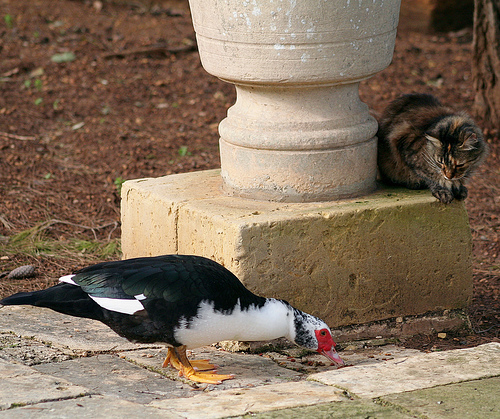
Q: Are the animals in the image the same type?
A: No, they are ducks and cats.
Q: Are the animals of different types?
A: Yes, they are ducks and cats.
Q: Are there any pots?
A: Yes, there is a pot.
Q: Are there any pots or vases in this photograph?
A: Yes, there is a pot.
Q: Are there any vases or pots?
A: Yes, there is a pot.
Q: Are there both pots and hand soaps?
A: No, there is a pot but no hand soaps.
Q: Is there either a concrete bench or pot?
A: Yes, there is a concrete pot.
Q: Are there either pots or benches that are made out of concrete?
A: Yes, the pot is made of concrete.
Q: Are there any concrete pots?
A: Yes, there is a pot that is made of concrete.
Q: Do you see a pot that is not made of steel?
A: Yes, there is a pot that is made of cement.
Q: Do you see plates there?
A: No, there are no plates.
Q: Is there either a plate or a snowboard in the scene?
A: No, there are no plates or snowboards.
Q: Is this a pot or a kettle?
A: This is a pot.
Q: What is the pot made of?
A: The pot is made of cement.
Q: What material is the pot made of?
A: The pot is made of cement.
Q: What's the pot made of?
A: The pot is made of concrete.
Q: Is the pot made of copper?
A: No, the pot is made of concrete.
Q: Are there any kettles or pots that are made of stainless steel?
A: No, there is a pot but it is made of concrete.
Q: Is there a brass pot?
A: No, there is a pot but it is made of concrete.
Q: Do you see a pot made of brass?
A: No, there is a pot but it is made of concrete.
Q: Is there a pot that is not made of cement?
A: No, there is a pot but it is made of cement.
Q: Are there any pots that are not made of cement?
A: No, there is a pot but it is made of cement.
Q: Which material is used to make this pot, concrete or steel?
A: The pot is made of concrete.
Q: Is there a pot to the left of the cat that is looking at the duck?
A: Yes, there is a pot to the left of the cat.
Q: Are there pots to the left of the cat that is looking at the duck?
A: Yes, there is a pot to the left of the cat.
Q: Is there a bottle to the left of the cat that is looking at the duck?
A: No, there is a pot to the left of the cat.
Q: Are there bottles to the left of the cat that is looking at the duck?
A: No, there is a pot to the left of the cat.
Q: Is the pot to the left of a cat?
A: Yes, the pot is to the left of a cat.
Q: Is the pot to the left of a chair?
A: No, the pot is to the left of a cat.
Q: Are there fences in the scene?
A: No, there are no fences.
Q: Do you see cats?
A: Yes, there is a cat.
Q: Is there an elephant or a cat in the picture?
A: Yes, there is a cat.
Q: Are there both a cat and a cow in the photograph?
A: No, there is a cat but no cows.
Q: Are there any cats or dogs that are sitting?
A: Yes, the cat is sitting.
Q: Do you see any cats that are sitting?
A: Yes, there is a cat that is sitting.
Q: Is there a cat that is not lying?
A: Yes, there is a cat that is sitting.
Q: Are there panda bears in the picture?
A: No, there are no panda bears.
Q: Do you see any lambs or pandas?
A: No, there are no pandas or lambs.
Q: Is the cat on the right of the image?
A: Yes, the cat is on the right of the image.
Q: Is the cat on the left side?
A: No, the cat is on the right of the image.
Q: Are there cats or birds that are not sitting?
A: No, there is a cat but it is sitting.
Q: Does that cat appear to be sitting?
A: Yes, the cat is sitting.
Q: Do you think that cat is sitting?
A: Yes, the cat is sitting.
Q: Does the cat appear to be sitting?
A: Yes, the cat is sitting.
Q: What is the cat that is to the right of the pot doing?
A: The cat is sitting.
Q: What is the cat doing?
A: The cat is sitting.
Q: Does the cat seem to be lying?
A: No, the cat is sitting.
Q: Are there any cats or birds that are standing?
A: No, there is a cat but it is sitting.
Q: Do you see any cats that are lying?
A: No, there is a cat but it is sitting.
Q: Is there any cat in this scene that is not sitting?
A: No, there is a cat but it is sitting.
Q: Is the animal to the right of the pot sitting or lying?
A: The cat is sitting.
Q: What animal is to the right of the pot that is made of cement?
A: The animal is a cat.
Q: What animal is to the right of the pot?
A: The animal is a cat.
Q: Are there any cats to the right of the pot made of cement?
A: Yes, there is a cat to the right of the pot.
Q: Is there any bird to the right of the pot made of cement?
A: No, there is a cat to the right of the pot.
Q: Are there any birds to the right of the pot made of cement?
A: No, there is a cat to the right of the pot.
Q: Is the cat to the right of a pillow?
A: No, the cat is to the right of the pot.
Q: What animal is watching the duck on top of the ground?
A: The cat is watching the duck.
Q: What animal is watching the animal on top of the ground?
A: The cat is watching the duck.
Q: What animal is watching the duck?
A: The cat is watching the duck.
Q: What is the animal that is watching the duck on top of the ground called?
A: The animal is a cat.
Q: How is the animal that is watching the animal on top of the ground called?
A: The animal is a cat.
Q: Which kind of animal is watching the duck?
A: The animal is a cat.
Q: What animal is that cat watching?
A: The cat is watching the duck.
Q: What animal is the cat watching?
A: The cat is watching the duck.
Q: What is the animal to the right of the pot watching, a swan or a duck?
A: The cat is watching a duck.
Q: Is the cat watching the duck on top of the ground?
A: Yes, the cat is watching the duck.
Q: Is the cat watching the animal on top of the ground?
A: Yes, the cat is watching the duck.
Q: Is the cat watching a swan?
A: No, the cat is watching the duck.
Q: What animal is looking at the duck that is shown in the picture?
A: The cat is looking at the duck.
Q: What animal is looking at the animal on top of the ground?
A: The cat is looking at the duck.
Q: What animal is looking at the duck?
A: The cat is looking at the duck.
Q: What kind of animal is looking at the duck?
A: The animal is a cat.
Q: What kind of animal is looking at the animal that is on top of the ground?
A: The animal is a cat.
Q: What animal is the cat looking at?
A: The cat is looking at the duck.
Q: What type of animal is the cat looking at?
A: The cat is looking at the duck.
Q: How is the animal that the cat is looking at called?
A: The animal is a duck.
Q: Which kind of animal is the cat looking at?
A: The cat is looking at the duck.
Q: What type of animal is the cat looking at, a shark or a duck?
A: The cat is looking at a duck.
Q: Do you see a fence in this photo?
A: No, there are no fences.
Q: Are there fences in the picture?
A: No, there are no fences.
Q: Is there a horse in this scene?
A: No, there are no horses.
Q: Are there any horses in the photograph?
A: No, there are no horses.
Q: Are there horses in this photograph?
A: No, there are no horses.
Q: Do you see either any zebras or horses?
A: No, there are no horses or zebras.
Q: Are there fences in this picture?
A: No, there are no fences.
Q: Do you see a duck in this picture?
A: Yes, there is a duck.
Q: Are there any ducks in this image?
A: Yes, there is a duck.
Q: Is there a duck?
A: Yes, there is a duck.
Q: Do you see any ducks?
A: Yes, there is a duck.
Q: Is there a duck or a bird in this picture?
A: Yes, there is a duck.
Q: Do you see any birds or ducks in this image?
A: Yes, there is a duck.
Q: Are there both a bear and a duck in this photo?
A: No, there is a duck but no bears.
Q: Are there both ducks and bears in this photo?
A: No, there is a duck but no bears.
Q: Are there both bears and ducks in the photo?
A: No, there is a duck but no bears.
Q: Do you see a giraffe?
A: No, there are no giraffes.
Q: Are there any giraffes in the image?
A: No, there are no giraffes.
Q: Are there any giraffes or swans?
A: No, there are no giraffes or swans.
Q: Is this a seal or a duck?
A: This is a duck.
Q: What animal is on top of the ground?
A: The duck is on top of the ground.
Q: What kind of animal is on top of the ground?
A: The animal is a duck.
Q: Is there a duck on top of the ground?
A: Yes, there is a duck on top of the ground.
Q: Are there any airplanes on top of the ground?
A: No, there is a duck on top of the ground.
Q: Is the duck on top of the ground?
A: Yes, the duck is on top of the ground.